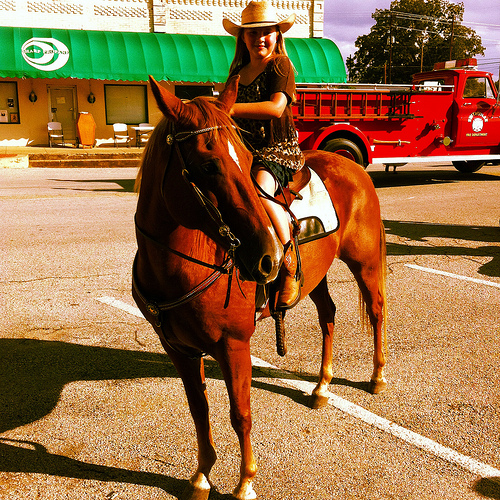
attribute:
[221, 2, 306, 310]
girl — focused, riding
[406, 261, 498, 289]
line — white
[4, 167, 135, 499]
ground — asphalt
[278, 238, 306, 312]
boot — brown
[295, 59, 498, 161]
firetruck — red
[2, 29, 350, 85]
awning — green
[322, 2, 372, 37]
sky — cloudy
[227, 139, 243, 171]
spot — diamond